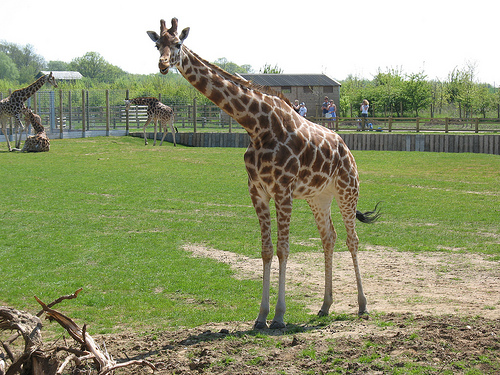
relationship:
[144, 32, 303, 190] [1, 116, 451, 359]
giraffe crouching crouching down at area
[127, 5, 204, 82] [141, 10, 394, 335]
head of giraffe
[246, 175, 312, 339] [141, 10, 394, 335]
front two legs of giraffe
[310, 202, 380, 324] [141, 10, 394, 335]
back two legs of giraffe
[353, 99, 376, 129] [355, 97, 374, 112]
person in a white in shirt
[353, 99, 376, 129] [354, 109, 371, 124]
person in a white in pants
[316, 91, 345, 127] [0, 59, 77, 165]
two people watching giraffes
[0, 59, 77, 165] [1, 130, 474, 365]
giraffes at zoo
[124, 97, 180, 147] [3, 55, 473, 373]
giraffe in exhibit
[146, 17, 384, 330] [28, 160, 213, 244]
brown  white giraffe standing in grassy field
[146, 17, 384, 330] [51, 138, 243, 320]
brown  white giraffe standing in field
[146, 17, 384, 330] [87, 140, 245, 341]
brown  white giraffe standing in field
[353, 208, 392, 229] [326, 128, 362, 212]
tail of a giraffe swinging on its rear end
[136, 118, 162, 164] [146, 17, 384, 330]
leg of a giraffe attached to brown  white giraffe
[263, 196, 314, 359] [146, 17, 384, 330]
leg of a giraffe supporting a brown  white giraffe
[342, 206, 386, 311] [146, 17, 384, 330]
leg of a giraffe supporting a brown  white giraffe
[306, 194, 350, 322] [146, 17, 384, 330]
leg of a giraffe supporting brown  white giraffe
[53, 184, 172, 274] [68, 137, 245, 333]
giraffe in a grassy standing in a grassy field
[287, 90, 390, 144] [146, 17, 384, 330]
people looking and observing a brown  white giraffe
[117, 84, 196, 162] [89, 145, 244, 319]
giraffe standing in a field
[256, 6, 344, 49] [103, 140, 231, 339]
white clouds hovering over a field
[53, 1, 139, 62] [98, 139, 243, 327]
louds in blue sky hovering over a green field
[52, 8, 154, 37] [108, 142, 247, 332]
blue sky above grassy field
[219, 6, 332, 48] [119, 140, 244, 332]
white clouds in above grassy field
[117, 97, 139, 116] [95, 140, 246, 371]
head of the giraffe high above ground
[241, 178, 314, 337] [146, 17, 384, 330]
legs of the giraffe supporting a brown  white giraffe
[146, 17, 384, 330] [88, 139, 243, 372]
brown  white giraffe standing in a green field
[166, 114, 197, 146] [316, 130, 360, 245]
"tail of the giraffe swinging on rear end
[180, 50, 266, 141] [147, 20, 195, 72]
neck of the giraffe supporting its head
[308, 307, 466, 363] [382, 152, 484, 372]
brown dirt lying on ground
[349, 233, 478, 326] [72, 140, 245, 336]
grass on the ground covering field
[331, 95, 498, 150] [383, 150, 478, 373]
fence in distance enclosing field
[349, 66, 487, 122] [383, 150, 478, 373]
trees in  distance growing in field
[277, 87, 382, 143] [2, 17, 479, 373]
people in distance walking in park